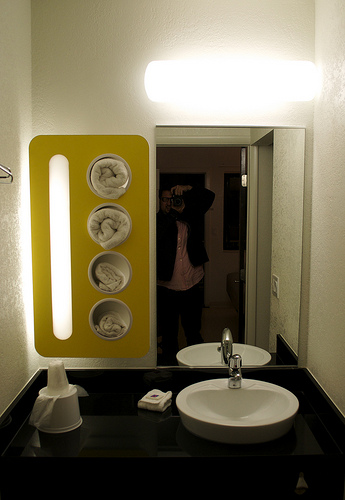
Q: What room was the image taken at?
A: It was taken at the bathroom.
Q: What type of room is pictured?
A: It is a bathroom.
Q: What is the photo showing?
A: It is showing a bathroom.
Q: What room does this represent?
A: It represents the bathroom.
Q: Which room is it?
A: It is a bathroom.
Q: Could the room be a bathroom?
A: Yes, it is a bathroom.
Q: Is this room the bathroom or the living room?
A: It is the bathroom.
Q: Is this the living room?
A: No, it is the bathroom.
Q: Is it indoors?
A: Yes, it is indoors.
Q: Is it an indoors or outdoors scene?
A: It is indoors.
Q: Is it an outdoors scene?
A: No, it is indoors.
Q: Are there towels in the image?
A: Yes, there is a towel.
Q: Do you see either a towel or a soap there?
A: Yes, there is a towel.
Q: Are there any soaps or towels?
A: Yes, there is a towel.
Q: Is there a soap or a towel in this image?
A: Yes, there is a towel.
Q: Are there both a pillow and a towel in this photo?
A: No, there is a towel but no pillows.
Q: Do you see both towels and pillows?
A: No, there is a towel but no pillows.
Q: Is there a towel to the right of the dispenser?
A: Yes, there is a towel to the right of the dispenser.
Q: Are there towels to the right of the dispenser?
A: Yes, there is a towel to the right of the dispenser.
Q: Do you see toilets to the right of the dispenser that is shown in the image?
A: No, there is a towel to the right of the dispenser.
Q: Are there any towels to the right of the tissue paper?
A: Yes, there is a towel to the right of the tissue paper.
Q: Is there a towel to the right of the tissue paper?
A: Yes, there is a towel to the right of the tissue paper.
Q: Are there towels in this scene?
A: Yes, there is a towel.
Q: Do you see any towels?
A: Yes, there is a towel.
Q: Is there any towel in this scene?
A: Yes, there is a towel.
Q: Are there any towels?
A: Yes, there is a towel.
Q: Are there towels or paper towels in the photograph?
A: Yes, there is a towel.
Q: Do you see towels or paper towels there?
A: Yes, there is a towel.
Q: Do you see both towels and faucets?
A: Yes, there are both a towel and a faucet.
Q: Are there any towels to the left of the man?
A: Yes, there is a towel to the left of the man.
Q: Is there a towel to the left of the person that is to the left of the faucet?
A: Yes, there is a towel to the left of the man.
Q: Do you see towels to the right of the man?
A: No, the towel is to the left of the man.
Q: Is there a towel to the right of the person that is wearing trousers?
A: No, the towel is to the left of the man.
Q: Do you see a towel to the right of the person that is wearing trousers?
A: No, the towel is to the left of the man.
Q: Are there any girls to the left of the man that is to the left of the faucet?
A: No, there is a towel to the left of the man.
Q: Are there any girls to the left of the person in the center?
A: No, there is a towel to the left of the man.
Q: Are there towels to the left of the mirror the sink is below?
A: Yes, there is a towel to the left of the mirror.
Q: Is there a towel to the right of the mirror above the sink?
A: No, the towel is to the left of the mirror.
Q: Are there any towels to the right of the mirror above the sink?
A: No, the towel is to the left of the mirror.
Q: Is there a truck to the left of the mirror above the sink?
A: No, there is a towel to the left of the mirror.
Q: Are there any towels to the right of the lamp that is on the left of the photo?
A: Yes, there is a towel to the right of the lamp.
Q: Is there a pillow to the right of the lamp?
A: No, there is a towel to the right of the lamp.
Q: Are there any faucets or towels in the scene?
A: Yes, there is a towel.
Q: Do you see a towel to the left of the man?
A: Yes, there is a towel to the left of the man.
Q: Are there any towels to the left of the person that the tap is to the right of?
A: Yes, there is a towel to the left of the man.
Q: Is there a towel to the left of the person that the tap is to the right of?
A: Yes, there is a towel to the left of the man.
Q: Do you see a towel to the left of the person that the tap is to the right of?
A: Yes, there is a towel to the left of the man.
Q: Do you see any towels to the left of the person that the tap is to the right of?
A: Yes, there is a towel to the left of the man.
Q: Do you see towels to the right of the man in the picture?
A: No, the towel is to the left of the man.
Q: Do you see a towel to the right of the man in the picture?
A: No, the towel is to the left of the man.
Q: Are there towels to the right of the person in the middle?
A: No, the towel is to the left of the man.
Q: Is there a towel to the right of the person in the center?
A: No, the towel is to the left of the man.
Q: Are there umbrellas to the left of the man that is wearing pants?
A: No, there is a towel to the left of the man.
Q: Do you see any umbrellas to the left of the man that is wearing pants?
A: No, there is a towel to the left of the man.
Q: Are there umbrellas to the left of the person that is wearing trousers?
A: No, there is a towel to the left of the man.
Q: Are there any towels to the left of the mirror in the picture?
A: Yes, there is a towel to the left of the mirror.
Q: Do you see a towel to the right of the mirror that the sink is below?
A: No, the towel is to the left of the mirror.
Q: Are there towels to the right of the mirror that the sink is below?
A: No, the towel is to the left of the mirror.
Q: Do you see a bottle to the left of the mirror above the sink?
A: No, there is a towel to the left of the mirror.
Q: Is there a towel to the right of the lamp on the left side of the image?
A: Yes, there is a towel to the right of the lamp.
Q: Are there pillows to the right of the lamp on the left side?
A: No, there is a towel to the right of the lamp.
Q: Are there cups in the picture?
A: Yes, there is a cup.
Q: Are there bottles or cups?
A: Yes, there is a cup.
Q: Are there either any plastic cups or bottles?
A: Yes, there is a plastic cup.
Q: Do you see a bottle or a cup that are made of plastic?
A: Yes, the cup is made of plastic.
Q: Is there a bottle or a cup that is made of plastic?
A: Yes, the cup is made of plastic.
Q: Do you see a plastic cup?
A: Yes, there is a cup that is made of plastic.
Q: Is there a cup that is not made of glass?
A: Yes, there is a cup that is made of plastic.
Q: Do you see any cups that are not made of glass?
A: Yes, there is a cup that is made of plastic.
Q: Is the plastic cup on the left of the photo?
A: Yes, the cup is on the left of the image.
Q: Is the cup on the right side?
A: No, the cup is on the left of the image.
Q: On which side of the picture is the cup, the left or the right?
A: The cup is on the left of the image.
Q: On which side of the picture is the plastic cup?
A: The cup is on the left of the image.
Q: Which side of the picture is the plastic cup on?
A: The cup is on the left of the image.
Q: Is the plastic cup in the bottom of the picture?
A: Yes, the cup is in the bottom of the image.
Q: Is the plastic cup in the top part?
A: No, the cup is in the bottom of the image.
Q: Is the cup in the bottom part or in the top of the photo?
A: The cup is in the bottom of the image.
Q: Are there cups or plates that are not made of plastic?
A: No, there is a cup but it is made of plastic.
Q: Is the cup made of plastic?
A: Yes, the cup is made of plastic.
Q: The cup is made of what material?
A: The cup is made of plastic.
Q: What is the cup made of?
A: The cup is made of plastic.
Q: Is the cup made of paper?
A: No, the cup is made of plastic.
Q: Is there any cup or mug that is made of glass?
A: No, there is a cup but it is made of plastic.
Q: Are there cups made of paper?
A: No, there is a cup but it is made of plastic.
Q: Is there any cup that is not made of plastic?
A: No, there is a cup but it is made of plastic.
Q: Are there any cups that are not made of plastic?
A: No, there is a cup but it is made of plastic.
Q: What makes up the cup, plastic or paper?
A: The cup is made of plastic.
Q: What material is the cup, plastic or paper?
A: The cup is made of plastic.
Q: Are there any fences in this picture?
A: No, there are no fences.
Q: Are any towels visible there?
A: Yes, there is a towel.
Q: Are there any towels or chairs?
A: Yes, there is a towel.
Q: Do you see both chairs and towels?
A: No, there is a towel but no chairs.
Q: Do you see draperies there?
A: No, there are no draperies.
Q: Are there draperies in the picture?
A: No, there are no draperies.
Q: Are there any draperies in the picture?
A: No, there are no draperies.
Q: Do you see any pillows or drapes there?
A: No, there are no drapes or pillows.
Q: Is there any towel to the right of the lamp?
A: Yes, there is a towel to the right of the lamp.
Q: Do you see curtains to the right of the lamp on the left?
A: No, there is a towel to the right of the lamp.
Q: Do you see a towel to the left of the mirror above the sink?
A: Yes, there is a towel to the left of the mirror.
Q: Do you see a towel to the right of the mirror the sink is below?
A: No, the towel is to the left of the mirror.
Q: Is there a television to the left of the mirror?
A: No, there is a towel to the left of the mirror.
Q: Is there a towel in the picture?
A: Yes, there is a towel.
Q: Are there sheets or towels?
A: Yes, there is a towel.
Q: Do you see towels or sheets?
A: Yes, there is a towel.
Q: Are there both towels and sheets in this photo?
A: No, there is a towel but no sheets.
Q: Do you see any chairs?
A: No, there are no chairs.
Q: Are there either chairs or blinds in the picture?
A: No, there are no chairs or blinds.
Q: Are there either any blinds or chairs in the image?
A: No, there are no chairs or blinds.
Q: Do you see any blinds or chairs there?
A: No, there are no chairs or blinds.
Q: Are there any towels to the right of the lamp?
A: Yes, there is a towel to the right of the lamp.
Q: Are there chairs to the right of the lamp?
A: No, there is a towel to the right of the lamp.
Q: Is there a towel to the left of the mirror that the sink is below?
A: Yes, there is a towel to the left of the mirror.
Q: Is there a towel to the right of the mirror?
A: No, the towel is to the left of the mirror.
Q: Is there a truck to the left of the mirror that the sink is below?
A: No, there is a towel to the left of the mirror.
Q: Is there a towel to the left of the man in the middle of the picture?
A: Yes, there is a towel to the left of the man.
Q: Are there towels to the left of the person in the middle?
A: Yes, there is a towel to the left of the man.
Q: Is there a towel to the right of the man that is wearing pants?
A: No, the towel is to the left of the man.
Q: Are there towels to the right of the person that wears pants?
A: No, the towel is to the left of the man.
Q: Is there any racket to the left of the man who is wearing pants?
A: No, there is a towel to the left of the man.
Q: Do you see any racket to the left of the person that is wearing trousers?
A: No, there is a towel to the left of the man.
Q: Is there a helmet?
A: No, there are no helmets.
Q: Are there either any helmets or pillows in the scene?
A: No, there are no helmets or pillows.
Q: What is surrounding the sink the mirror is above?
A: The counter is surrounding the sink.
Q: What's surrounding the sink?
A: The counter is surrounding the sink.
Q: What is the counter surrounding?
A: The counter is surrounding the sink.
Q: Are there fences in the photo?
A: No, there are no fences.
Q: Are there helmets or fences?
A: No, there are no fences or helmets.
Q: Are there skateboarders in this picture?
A: No, there are no skateboarders.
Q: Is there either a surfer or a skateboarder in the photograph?
A: No, there are no skateboarders or surfers.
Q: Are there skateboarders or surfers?
A: No, there are no skateboarders or surfers.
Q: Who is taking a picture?
A: The man is taking a picture.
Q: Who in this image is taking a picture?
A: The man is taking a picture.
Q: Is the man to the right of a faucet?
A: No, the man is to the left of a faucet.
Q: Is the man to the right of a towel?
A: Yes, the man is to the right of a towel.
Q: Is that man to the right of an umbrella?
A: No, the man is to the right of a towel.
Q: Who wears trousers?
A: The man wears trousers.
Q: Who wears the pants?
A: The man wears trousers.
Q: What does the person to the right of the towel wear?
A: The man wears trousers.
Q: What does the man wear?
A: The man wears trousers.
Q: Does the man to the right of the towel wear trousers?
A: Yes, the man wears trousers.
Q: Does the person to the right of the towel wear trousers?
A: Yes, the man wears trousers.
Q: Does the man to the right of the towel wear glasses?
A: No, the man wears trousers.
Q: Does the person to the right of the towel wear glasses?
A: No, the man wears trousers.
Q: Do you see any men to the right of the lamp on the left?
A: Yes, there is a man to the right of the lamp.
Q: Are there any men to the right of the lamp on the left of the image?
A: Yes, there is a man to the right of the lamp.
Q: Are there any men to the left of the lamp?
A: No, the man is to the right of the lamp.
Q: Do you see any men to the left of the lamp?
A: No, the man is to the right of the lamp.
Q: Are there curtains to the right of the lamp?
A: No, there is a man to the right of the lamp.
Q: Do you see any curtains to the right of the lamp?
A: No, there is a man to the right of the lamp.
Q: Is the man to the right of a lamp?
A: Yes, the man is to the right of a lamp.